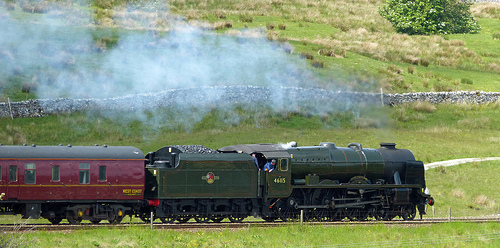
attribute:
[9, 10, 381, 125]
smoke — large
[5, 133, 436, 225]
train — old, brown, chugging, green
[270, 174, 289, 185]
numbers — yellow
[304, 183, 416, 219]
wheels — large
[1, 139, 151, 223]
train car — red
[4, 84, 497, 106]
wall — stone, hillside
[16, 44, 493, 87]
grass — green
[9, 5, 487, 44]
grass — green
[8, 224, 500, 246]
grass — green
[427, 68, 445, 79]
grass — green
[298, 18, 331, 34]
grass — green, hill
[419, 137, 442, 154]
grass — green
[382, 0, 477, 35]
bush — large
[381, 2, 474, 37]
tree — large